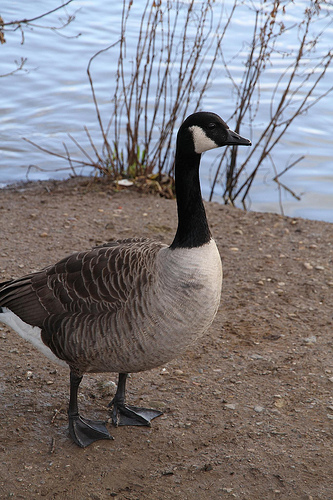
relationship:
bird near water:
[0, 110, 251, 448] [1, 1, 332, 228]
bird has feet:
[0, 110, 251, 448] [56, 396, 166, 452]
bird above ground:
[0, 110, 251, 448] [1, 176, 332, 500]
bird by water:
[0, 110, 251, 448] [1, 1, 332, 228]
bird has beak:
[0, 110, 251, 448] [224, 125, 253, 152]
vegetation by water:
[23, 0, 332, 210] [1, 1, 332, 228]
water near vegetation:
[1, 1, 332, 228] [23, 0, 332, 210]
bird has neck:
[0, 110, 251, 448] [173, 149, 216, 251]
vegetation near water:
[23, 0, 332, 210] [1, 1, 332, 228]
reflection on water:
[271, 177, 307, 204] [1, 1, 332, 228]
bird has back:
[0, 110, 251, 448] [1, 240, 165, 326]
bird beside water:
[0, 110, 251, 448] [1, 1, 332, 228]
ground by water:
[1, 176, 332, 500] [1, 1, 332, 228]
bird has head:
[0, 110, 251, 448] [174, 111, 254, 156]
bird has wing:
[0, 110, 251, 448] [1, 273, 154, 328]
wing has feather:
[1, 273, 154, 328] [35, 287, 58, 304]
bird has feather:
[0, 110, 251, 448] [35, 287, 58, 304]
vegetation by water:
[23, 0, 332, 210] [1, 1, 332, 114]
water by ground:
[1, 1, 332, 228] [1, 176, 332, 500]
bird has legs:
[0, 110, 251, 448] [67, 373, 129, 416]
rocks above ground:
[298, 258, 327, 275] [1, 176, 332, 500]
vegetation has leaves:
[23, 0, 332, 210] [252, 4, 322, 69]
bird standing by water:
[0, 110, 251, 448] [1, 1, 332, 114]